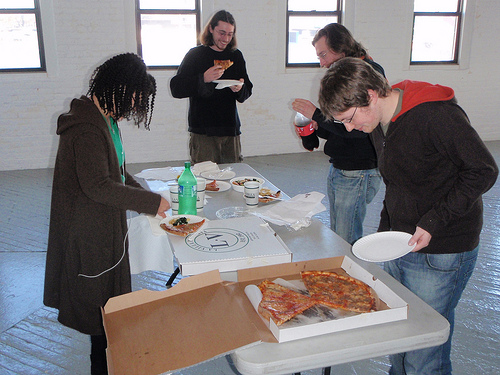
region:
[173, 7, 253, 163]
Man holding a plate and a piece of pizza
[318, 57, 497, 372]
Man looking at the pizza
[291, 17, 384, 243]
Man holding a cola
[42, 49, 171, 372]
Woman wearing headphones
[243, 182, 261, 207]
Paper cup on the table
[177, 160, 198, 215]
Green bottle on the table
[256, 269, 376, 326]
Pizza in a paper box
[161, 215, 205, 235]
Paper plate with pizza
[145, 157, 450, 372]
Gray table in the room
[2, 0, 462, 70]
Windows on the wall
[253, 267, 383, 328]
partially eaten cheese pizza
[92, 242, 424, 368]
a white pizza box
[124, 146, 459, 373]
a white picnic table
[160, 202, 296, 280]
a closed pizza box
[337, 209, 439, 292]
an empty pizza plate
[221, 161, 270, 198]
a white food bowl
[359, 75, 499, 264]
a boy's black hoodie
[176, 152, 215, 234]
a green sprite bottle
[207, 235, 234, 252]
the letter L in black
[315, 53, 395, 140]
man wearing glasses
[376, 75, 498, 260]
hoodie sweatshirt with red lining in hood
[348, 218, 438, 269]
hand holding white paper plate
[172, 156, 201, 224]
green plastic soda bottle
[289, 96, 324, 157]
plastic bottle with cola inside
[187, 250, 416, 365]
large pizza with several slices missing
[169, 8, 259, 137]
man with long hair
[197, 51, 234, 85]
hand holding folded pizza slice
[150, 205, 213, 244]
slice of pizza on a paper plate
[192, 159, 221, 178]
stack of paper napkins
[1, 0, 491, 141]
The wall is brick.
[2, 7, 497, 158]
The walls are white.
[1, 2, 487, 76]
Windows on the wall.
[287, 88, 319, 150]
Man holding coke bottle.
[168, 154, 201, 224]
Sprite bottle on table.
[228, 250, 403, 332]
Pizza in a box.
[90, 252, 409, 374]
Pizza box is cardboard.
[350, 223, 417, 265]
The plate is white.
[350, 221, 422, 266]
The plate is round.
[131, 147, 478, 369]
The table is white.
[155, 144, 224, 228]
a sprite bottle is on the table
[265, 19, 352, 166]
the man is holding the coca cola bottle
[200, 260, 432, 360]
the pizza box is open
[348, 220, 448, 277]
the young man is holding a plate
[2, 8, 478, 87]
the windows are closed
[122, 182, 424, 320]
two pizza boxes are on the table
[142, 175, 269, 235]
three white cups are on the table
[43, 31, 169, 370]
the woman is standing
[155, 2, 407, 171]
the three men are wearing glasses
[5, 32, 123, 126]
the walls are made of brick